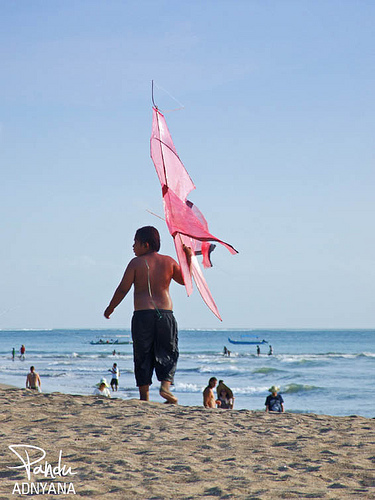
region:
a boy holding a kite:
[92, 73, 242, 405]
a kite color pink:
[139, 76, 242, 326]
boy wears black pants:
[102, 228, 195, 404]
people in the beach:
[0, 366, 295, 426]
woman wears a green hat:
[88, 372, 115, 403]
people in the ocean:
[4, 323, 300, 372]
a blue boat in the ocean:
[219, 330, 273, 346]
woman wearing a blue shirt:
[259, 380, 289, 413]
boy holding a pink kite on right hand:
[95, 76, 246, 409]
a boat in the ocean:
[84, 330, 132, 351]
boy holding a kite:
[91, 95, 216, 409]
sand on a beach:
[3, 382, 374, 497]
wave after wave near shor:
[23, 345, 350, 396]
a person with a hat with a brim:
[255, 380, 290, 418]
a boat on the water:
[219, 334, 274, 349]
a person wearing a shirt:
[251, 376, 294, 426]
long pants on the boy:
[126, 308, 177, 407]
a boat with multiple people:
[80, 333, 142, 348]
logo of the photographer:
[9, 442, 90, 497]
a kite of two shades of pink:
[137, 82, 238, 316]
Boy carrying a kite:
[87, 80, 228, 411]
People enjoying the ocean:
[2, 340, 125, 391]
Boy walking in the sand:
[93, 217, 208, 425]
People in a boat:
[85, 332, 135, 349]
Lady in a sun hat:
[215, 376, 236, 412]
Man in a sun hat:
[262, 383, 289, 413]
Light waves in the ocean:
[186, 348, 373, 404]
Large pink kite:
[133, 69, 247, 326]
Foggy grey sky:
[1, 11, 373, 318]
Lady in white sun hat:
[88, 375, 112, 399]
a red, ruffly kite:
[125, 92, 277, 355]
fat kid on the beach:
[110, 216, 233, 471]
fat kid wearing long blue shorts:
[117, 291, 179, 400]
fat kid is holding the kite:
[100, 216, 180, 411]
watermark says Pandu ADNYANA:
[6, 423, 87, 495]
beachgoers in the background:
[184, 368, 301, 412]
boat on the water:
[216, 327, 295, 363]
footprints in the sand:
[46, 412, 219, 492]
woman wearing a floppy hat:
[75, 366, 112, 405]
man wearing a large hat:
[263, 372, 309, 450]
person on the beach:
[90, 219, 205, 407]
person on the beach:
[263, 383, 288, 420]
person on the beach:
[213, 385, 238, 412]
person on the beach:
[200, 375, 218, 410]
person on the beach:
[107, 358, 122, 391]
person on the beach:
[92, 374, 111, 402]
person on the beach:
[23, 364, 44, 394]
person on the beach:
[18, 342, 28, 365]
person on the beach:
[7, 341, 17, 361]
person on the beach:
[108, 344, 119, 357]